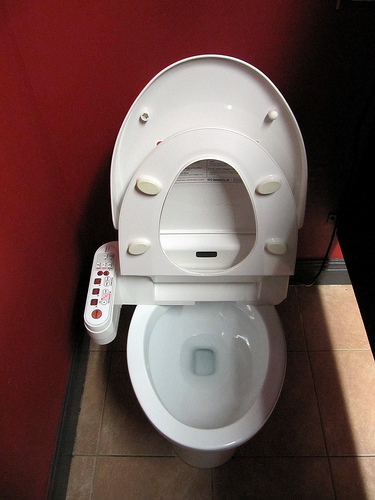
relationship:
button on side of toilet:
[91, 309, 103, 319] [83, 53, 310, 470]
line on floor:
[95, 453, 329, 462] [67, 284, 374, 498]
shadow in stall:
[80, 146, 371, 499] [1, 8, 366, 490]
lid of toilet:
[107, 57, 309, 275] [83, 53, 310, 470]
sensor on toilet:
[193, 250, 217, 258] [83, 53, 310, 470]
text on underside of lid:
[177, 160, 239, 183] [107, 57, 309, 275]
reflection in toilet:
[230, 331, 254, 348] [83, 53, 310, 470]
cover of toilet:
[109, 53, 308, 282] [83, 53, 310, 470]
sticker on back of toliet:
[174, 160, 245, 184] [83, 53, 310, 468]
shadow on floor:
[80, 146, 371, 499] [282, 283, 372, 497]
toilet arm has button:
[84, 240, 119, 345] [91, 309, 103, 319]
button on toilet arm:
[91, 309, 103, 319] [84, 240, 119, 345]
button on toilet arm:
[88, 296, 98, 308] [84, 240, 119, 345]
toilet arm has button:
[84, 240, 119, 345] [88, 296, 98, 308]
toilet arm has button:
[84, 240, 119, 345] [92, 276, 99, 286]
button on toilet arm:
[92, 276, 99, 286] [84, 240, 119, 345]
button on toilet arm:
[96, 270, 104, 276] [84, 240, 119, 345]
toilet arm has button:
[84, 240, 119, 345] [96, 270, 104, 276]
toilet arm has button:
[84, 240, 119, 345] [100, 298, 108, 306]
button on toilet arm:
[100, 298, 108, 306] [84, 240, 119, 345]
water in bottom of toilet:
[179, 336, 233, 383] [126, 303, 287, 469]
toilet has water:
[126, 303, 287, 469] [179, 336, 233, 383]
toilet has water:
[83, 53, 310, 470] [185, 346, 217, 374]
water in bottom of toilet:
[185, 346, 217, 374] [83, 53, 310, 470]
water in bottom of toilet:
[179, 336, 233, 383] [83, 53, 310, 470]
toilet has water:
[83, 53, 310, 470] [179, 336, 233, 383]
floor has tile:
[67, 284, 374, 498] [90, 456, 212, 498]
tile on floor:
[90, 456, 212, 498] [67, 284, 374, 498]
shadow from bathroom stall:
[80, 146, 371, 499] [19, 16, 355, 472]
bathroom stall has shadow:
[19, 16, 355, 472] [80, 146, 371, 499]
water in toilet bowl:
[179, 336, 233, 383] [126, 307, 286, 464]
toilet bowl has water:
[126, 307, 286, 464] [179, 336, 233, 383]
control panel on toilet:
[83, 242, 117, 328] [83, 53, 310, 470]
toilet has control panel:
[83, 53, 310, 470] [83, 242, 117, 328]